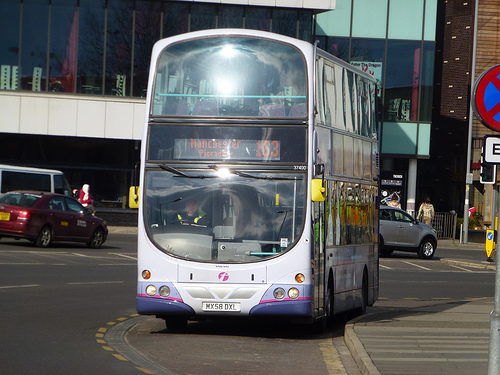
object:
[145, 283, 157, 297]
light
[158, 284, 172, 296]
light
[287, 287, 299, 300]
light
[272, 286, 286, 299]
light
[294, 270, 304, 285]
light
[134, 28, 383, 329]
bus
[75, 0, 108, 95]
window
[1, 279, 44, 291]
lines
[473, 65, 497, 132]
sign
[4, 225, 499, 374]
road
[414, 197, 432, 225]
person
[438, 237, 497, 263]
sidewalk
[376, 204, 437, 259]
car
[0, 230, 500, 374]
street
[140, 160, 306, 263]
windshield